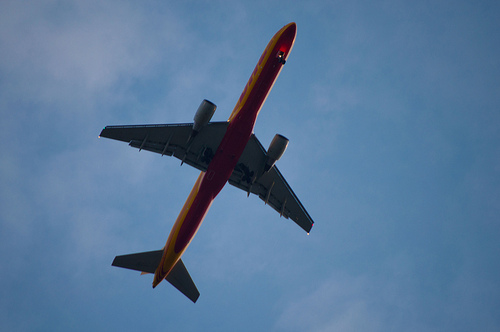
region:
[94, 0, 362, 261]
large plane in sky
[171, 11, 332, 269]
orange body on plane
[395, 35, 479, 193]
sky is blue and white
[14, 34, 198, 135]
few clouds in sky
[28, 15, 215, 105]
clouds are white and thin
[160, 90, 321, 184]
two engines on plane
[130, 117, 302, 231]
white wings on plane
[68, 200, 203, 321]
orange tail on plane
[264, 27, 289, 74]
red light on plane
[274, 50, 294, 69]
black wheels on plane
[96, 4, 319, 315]
airplane in the sky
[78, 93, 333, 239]
two wings on either side of the plane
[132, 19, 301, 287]
body of the plane is narrow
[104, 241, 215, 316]
tail of the plane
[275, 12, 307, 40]
nose of the plane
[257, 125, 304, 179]
jet engine under the wing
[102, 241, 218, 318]
two small wings on the tail of the plane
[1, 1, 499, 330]
thin clouds in the sky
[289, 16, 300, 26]
sharp point of the nose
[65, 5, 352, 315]
bottom of the plane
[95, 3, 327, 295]
plane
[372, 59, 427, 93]
white clouds in blue sky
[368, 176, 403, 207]
white clouds in blue sky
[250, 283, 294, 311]
white clouds in blue sky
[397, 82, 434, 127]
white clouds in blue sky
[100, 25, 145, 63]
white clouds in blue sky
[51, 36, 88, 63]
white clouds in blue sky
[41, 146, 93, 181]
white clouds in blue sky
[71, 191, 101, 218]
white clouds in blue sky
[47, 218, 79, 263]
white clouds in blue sky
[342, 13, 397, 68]
white clouds in blue sky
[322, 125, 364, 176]
white clouds in blue sky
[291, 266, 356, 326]
white clouds in blue sky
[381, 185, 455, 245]
white clouds in blue sky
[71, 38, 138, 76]
white clouds in blue sky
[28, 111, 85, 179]
white clouds in blue sky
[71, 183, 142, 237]
white clouds in blue sky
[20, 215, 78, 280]
white clouds in blue sky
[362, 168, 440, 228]
white clouds in blue sky